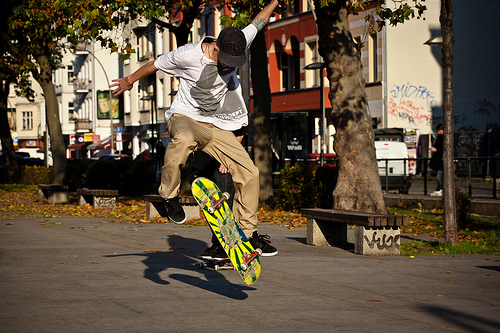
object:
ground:
[27, 267, 495, 326]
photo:
[0, 0, 495, 331]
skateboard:
[189, 176, 263, 286]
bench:
[76, 187, 120, 210]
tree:
[246, 0, 433, 215]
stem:
[360, 14, 373, 44]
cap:
[214, 25, 247, 67]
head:
[214, 26, 248, 69]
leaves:
[42, 214, 57, 218]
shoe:
[160, 196, 188, 225]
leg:
[157, 138, 199, 225]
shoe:
[247, 229, 280, 257]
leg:
[202, 135, 278, 258]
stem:
[94, 23, 137, 64]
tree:
[0, 0, 113, 188]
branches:
[37, 17, 116, 43]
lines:
[221, 200, 227, 212]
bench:
[299, 207, 411, 257]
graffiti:
[363, 231, 401, 251]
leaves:
[54, 222, 64, 226]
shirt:
[154, 23, 259, 132]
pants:
[157, 112, 262, 240]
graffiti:
[398, 111, 414, 124]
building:
[114, 4, 498, 178]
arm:
[241, 0, 283, 49]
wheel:
[239, 262, 249, 272]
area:
[27, 239, 159, 315]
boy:
[107, 18, 280, 258]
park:
[0, 144, 499, 333]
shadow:
[101, 234, 260, 303]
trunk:
[313, 1, 391, 216]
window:
[303, 35, 320, 89]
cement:
[110, 288, 302, 314]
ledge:
[247, 85, 337, 114]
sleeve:
[153, 46, 180, 77]